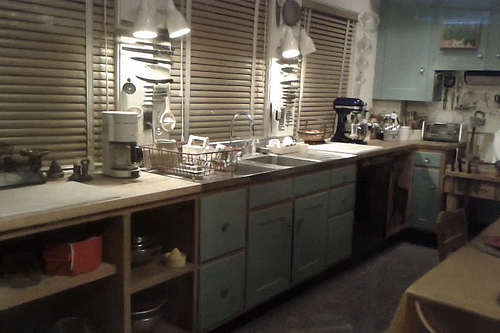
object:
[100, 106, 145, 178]
coffee maker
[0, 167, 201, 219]
counter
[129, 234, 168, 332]
bowls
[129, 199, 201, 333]
shelf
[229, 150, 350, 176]
sink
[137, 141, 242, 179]
dish rack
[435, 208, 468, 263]
chair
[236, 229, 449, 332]
ground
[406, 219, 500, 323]
table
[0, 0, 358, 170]
blinds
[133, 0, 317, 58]
light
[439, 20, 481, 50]
painting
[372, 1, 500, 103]
cupboard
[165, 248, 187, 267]
fruit juicer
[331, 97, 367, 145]
mixer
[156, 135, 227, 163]
dishes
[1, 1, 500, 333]
kitchen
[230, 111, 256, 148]
faucet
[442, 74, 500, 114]
utensils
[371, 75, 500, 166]
wall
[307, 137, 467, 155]
counter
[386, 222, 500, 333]
tablecloth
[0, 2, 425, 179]
wall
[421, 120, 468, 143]
toaster oven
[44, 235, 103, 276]
pot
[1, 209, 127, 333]
shelf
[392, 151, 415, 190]
towel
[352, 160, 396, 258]
oven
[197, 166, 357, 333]
cabinets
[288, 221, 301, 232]
handle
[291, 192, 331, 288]
cabinet door